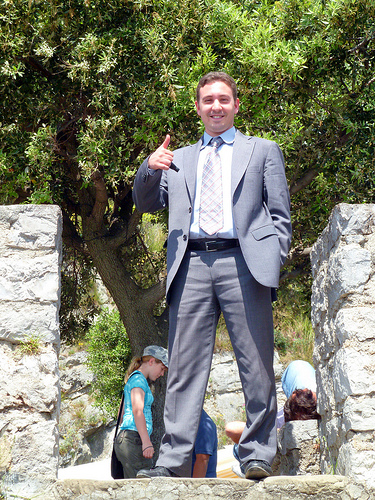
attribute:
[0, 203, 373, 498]
wall — rock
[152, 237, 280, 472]
pants — grey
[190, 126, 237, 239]
shirt — blue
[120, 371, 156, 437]
shirt — blue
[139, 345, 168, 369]
hat — faded, camouflage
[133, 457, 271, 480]
shoes — black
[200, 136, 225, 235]
tie — plaid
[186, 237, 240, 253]
belt — black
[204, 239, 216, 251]
buckle — silver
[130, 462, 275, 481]
shoes — black, leather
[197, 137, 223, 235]
tie — blue, red, white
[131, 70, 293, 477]
man — standing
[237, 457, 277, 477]
shoe — black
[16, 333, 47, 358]
plant — small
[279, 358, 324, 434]
lady — Bending 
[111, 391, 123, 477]
purse — black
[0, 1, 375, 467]
tree — green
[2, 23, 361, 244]
tree — green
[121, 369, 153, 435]
t-shirt — blue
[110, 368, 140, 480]
purse — black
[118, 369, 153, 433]
shirt — blue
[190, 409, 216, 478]
shirt — blue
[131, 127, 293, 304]
jacket — gray, suit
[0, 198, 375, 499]
rock wall — white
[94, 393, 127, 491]
purse — black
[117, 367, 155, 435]
shirt — Turquoise 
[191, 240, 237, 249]
belt — black, leather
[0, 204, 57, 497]
wall — brick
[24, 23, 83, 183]
rope — black